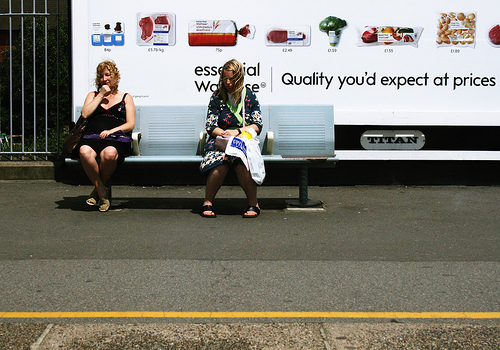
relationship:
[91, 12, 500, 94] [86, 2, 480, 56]
billboard adverting groceries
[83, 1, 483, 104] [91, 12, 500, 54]
billboard praing quality and prices of ir groceries